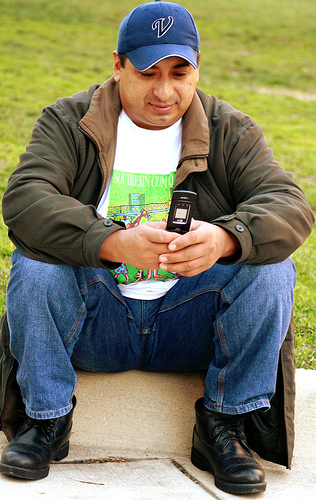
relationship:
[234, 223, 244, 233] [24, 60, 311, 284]
button on jacket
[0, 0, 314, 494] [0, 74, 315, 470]
man wearing coat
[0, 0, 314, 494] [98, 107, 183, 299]
man wearing t shirt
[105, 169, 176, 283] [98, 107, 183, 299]
picture on t shirt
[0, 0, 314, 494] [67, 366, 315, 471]
man sitting on curb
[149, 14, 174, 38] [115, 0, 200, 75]
logo on blue hat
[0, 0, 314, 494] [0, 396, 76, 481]
man wearing shoe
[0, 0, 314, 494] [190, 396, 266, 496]
man wearing black shoe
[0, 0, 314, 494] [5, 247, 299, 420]
man wearing jeans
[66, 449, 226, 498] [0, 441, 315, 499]
crack in concrete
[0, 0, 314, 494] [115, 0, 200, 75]
man wearing blue hat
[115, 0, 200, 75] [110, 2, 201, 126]
blue hat on head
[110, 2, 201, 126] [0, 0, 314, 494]
head on man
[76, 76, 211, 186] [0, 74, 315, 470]
collar on coat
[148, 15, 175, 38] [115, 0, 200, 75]
v on blue hat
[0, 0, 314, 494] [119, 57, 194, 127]
man has face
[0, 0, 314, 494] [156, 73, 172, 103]
man has nose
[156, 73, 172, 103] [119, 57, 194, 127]
nose on face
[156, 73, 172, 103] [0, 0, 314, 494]
nose on man